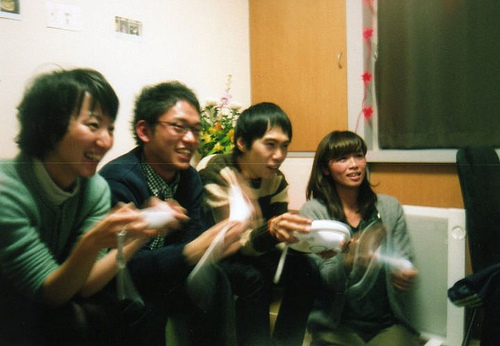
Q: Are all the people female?
A: No, they are both male and female.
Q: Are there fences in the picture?
A: No, there are no fences.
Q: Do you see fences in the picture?
A: No, there are no fences.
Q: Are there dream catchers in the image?
A: No, there are no dream catchers.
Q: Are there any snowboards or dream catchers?
A: No, there are no dream catchers or snowboards.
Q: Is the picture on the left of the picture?
A: Yes, the picture is on the left of the image.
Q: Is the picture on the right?
A: No, the picture is on the left of the image.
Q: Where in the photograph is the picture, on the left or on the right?
A: The picture is on the left of the image.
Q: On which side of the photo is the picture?
A: The picture is on the left of the image.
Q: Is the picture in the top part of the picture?
A: Yes, the picture is in the top of the image.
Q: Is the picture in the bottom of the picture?
A: No, the picture is in the top of the image.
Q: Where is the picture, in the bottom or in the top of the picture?
A: The picture is in the top of the image.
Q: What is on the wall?
A: The picture is on the wall.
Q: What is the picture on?
A: The picture is on the wall.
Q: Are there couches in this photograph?
A: No, there are no couches.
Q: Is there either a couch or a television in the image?
A: No, there are no couches or televisions.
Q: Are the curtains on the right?
A: Yes, the curtains are on the right of the image.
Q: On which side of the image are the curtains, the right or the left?
A: The curtains are on the right of the image.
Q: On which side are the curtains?
A: The curtains are on the right of the image.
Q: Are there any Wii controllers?
A: Yes, there is a Wii controller.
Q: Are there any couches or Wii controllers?
A: Yes, there is a Wii controller.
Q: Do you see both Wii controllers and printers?
A: No, there is a Wii controller but no printers.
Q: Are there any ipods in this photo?
A: No, there are no ipods.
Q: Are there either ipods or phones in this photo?
A: No, there are no ipods or phones.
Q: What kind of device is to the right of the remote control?
A: The device is a Wii controller.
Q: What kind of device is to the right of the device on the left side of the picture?
A: The device is a Wii controller.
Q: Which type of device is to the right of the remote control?
A: The device is a Wii controller.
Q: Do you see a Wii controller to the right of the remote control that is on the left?
A: Yes, there is a Wii controller to the right of the remote control.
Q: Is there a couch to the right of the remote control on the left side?
A: No, there is a Wii controller to the right of the remote.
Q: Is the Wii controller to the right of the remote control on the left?
A: Yes, the Wii controller is to the right of the remote.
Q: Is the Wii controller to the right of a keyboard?
A: No, the Wii controller is to the right of the remote.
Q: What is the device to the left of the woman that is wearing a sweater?
A: The device is a Wii controller.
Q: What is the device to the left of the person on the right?
A: The device is a Wii controller.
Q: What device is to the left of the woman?
A: The device is a Wii controller.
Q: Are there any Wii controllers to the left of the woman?
A: Yes, there is a Wii controller to the left of the woman.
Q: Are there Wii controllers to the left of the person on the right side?
A: Yes, there is a Wii controller to the left of the woman.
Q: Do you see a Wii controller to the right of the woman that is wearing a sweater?
A: No, the Wii controller is to the left of the woman.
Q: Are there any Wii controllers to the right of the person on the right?
A: No, the Wii controller is to the left of the woman.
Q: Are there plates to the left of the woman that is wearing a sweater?
A: No, there is a Wii controller to the left of the woman.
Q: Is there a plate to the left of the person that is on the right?
A: No, there is a Wii controller to the left of the woman.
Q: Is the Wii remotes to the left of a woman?
A: Yes, the Wii remotes is to the left of a woman.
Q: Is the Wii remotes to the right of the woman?
A: No, the Wii remotes is to the left of the woman.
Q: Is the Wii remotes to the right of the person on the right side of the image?
A: No, the Wii remotes is to the left of the woman.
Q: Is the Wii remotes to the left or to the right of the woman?
A: The Wii remotes is to the left of the woman.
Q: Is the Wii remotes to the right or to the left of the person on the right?
A: The Wii remotes is to the left of the woman.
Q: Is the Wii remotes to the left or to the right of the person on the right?
A: The Wii remotes is to the left of the woman.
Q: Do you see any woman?
A: Yes, there is a woman.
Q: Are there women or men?
A: Yes, there is a woman.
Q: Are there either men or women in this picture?
A: Yes, there is a woman.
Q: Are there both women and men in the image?
A: Yes, there are both a woman and a man.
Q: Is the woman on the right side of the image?
A: Yes, the woman is on the right of the image.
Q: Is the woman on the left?
A: No, the woman is on the right of the image.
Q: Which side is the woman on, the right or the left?
A: The woman is on the right of the image.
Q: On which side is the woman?
A: The woman is on the right of the image.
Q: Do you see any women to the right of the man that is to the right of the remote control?
A: Yes, there is a woman to the right of the man.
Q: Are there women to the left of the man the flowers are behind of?
A: No, the woman is to the right of the man.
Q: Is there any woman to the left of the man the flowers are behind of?
A: No, the woman is to the right of the man.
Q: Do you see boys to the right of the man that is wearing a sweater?
A: No, there is a woman to the right of the man.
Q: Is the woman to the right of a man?
A: Yes, the woman is to the right of a man.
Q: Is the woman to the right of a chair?
A: No, the woman is to the right of a man.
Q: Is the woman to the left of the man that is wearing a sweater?
A: No, the woman is to the right of the man.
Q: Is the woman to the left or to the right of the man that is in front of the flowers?
A: The woman is to the right of the man.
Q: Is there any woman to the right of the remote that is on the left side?
A: Yes, there is a woman to the right of the remote control.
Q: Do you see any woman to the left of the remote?
A: No, the woman is to the right of the remote.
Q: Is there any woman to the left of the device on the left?
A: No, the woman is to the right of the remote.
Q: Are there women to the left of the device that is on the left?
A: No, the woman is to the right of the remote.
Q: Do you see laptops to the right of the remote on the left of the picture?
A: No, there is a woman to the right of the remote.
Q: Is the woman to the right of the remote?
A: Yes, the woman is to the right of the remote.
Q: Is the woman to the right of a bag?
A: No, the woman is to the right of the remote.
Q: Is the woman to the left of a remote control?
A: No, the woman is to the right of a remote control.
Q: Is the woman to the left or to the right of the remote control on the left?
A: The woman is to the right of the remote.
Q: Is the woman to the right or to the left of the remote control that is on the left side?
A: The woman is to the right of the remote.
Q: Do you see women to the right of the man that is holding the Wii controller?
A: Yes, there is a woman to the right of the man.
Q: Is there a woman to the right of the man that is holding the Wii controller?
A: Yes, there is a woman to the right of the man.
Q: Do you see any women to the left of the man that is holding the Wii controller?
A: No, the woman is to the right of the man.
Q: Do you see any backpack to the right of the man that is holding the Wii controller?
A: No, there is a woman to the right of the man.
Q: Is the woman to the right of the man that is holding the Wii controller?
A: Yes, the woman is to the right of the man.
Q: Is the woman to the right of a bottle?
A: No, the woman is to the right of the man.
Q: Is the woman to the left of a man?
A: No, the woman is to the right of a man.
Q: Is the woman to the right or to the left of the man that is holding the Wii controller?
A: The woman is to the right of the man.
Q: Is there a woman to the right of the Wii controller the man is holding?
A: Yes, there is a woman to the right of the Wii controller.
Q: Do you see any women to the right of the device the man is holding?
A: Yes, there is a woman to the right of the Wii controller.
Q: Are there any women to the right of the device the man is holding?
A: Yes, there is a woman to the right of the Wii controller.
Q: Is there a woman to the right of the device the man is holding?
A: Yes, there is a woman to the right of the Wii controller.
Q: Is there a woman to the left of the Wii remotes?
A: No, the woman is to the right of the Wii remotes.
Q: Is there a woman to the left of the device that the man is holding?
A: No, the woman is to the right of the Wii remotes.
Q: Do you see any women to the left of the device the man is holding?
A: No, the woman is to the right of the Wii remotes.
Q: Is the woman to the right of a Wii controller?
A: Yes, the woman is to the right of a Wii controller.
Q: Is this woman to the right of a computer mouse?
A: No, the woman is to the right of a Wii controller.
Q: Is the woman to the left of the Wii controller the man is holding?
A: No, the woman is to the right of the Wii remotes.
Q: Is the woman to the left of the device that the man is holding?
A: No, the woman is to the right of the Wii remotes.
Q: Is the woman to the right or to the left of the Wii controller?
A: The woman is to the right of the Wii controller.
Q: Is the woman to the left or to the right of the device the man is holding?
A: The woman is to the right of the Wii controller.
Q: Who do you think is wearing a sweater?
A: The woman is wearing a sweater.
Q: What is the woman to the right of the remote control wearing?
A: The woman is wearing a sweater.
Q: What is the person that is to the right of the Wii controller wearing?
A: The woman is wearing a sweater.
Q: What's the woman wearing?
A: The woman is wearing a sweater.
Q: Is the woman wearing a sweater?
A: Yes, the woman is wearing a sweater.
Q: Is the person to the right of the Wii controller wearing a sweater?
A: Yes, the woman is wearing a sweater.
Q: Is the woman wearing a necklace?
A: No, the woman is wearing a sweater.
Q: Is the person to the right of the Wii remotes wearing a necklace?
A: No, the woman is wearing a sweater.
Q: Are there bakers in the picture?
A: No, there are no bakers.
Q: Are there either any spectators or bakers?
A: No, there are no bakers or spectators.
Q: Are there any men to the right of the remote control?
A: Yes, there is a man to the right of the remote control.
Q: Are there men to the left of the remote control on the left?
A: No, the man is to the right of the remote control.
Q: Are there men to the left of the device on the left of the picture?
A: No, the man is to the right of the remote control.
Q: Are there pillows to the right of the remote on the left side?
A: No, there is a man to the right of the remote control.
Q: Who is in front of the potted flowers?
A: The man is in front of the flowers.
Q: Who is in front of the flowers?
A: The man is in front of the flowers.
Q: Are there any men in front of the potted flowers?
A: Yes, there is a man in front of the flowers.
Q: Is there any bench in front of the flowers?
A: No, there is a man in front of the flowers.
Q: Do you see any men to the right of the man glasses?
A: Yes, there is a man to the right of the glasses.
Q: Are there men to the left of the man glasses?
A: No, the man is to the right of the glasses.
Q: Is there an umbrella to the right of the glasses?
A: No, there is a man to the right of the glasses.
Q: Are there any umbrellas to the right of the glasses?
A: No, there is a man to the right of the glasses.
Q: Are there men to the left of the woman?
A: Yes, there is a man to the left of the woman.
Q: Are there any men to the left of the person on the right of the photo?
A: Yes, there is a man to the left of the woman.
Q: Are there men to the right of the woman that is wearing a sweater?
A: No, the man is to the left of the woman.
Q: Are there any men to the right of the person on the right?
A: No, the man is to the left of the woman.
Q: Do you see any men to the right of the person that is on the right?
A: No, the man is to the left of the woman.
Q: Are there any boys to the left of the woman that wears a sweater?
A: No, there is a man to the left of the woman.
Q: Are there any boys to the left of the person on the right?
A: No, there is a man to the left of the woman.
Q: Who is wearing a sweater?
A: The man is wearing a sweater.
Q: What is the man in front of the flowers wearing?
A: The man is wearing a sweater.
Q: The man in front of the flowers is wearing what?
A: The man is wearing a sweater.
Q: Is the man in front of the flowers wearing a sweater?
A: Yes, the man is wearing a sweater.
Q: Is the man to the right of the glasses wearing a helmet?
A: No, the man is wearing a sweater.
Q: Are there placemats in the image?
A: No, there are no placemats.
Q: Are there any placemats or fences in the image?
A: No, there are no placemats or fences.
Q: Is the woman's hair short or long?
A: The hair is long.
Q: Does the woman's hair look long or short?
A: The hair is long.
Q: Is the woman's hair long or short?
A: The hair is long.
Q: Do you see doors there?
A: Yes, there is a door.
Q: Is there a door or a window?
A: Yes, there is a door.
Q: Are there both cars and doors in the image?
A: No, there is a door but no cars.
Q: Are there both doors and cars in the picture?
A: No, there is a door but no cars.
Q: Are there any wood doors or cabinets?
A: Yes, there is a wood door.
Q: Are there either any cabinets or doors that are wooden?
A: Yes, the door is wooden.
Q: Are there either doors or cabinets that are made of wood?
A: Yes, the door is made of wood.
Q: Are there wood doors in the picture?
A: Yes, there is a wood door.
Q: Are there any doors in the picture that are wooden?
A: Yes, there is a door that is wooden.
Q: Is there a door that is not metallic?
A: Yes, there is a wooden door.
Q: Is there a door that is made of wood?
A: Yes, there is a door that is made of wood.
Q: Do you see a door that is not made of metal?
A: Yes, there is a door that is made of wood.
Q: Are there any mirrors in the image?
A: No, there are no mirrors.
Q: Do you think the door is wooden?
A: Yes, the door is wooden.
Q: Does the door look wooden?
A: Yes, the door is wooden.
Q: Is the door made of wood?
A: Yes, the door is made of wood.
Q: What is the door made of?
A: The door is made of wood.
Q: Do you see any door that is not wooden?
A: No, there is a door but it is wooden.